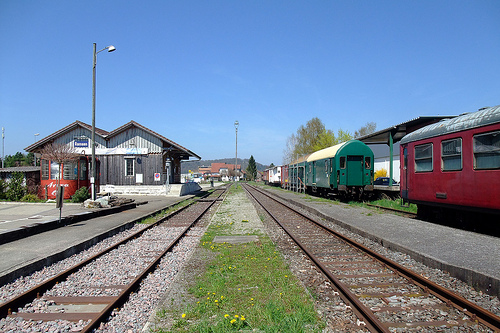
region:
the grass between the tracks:
[164, 232, 316, 330]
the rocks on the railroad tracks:
[0, 222, 211, 331]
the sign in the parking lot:
[51, 184, 66, 220]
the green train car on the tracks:
[286, 153, 374, 196]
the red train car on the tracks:
[396, 123, 498, 208]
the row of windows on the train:
[414, 125, 498, 167]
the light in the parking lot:
[93, 26, 115, 205]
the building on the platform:
[102, 119, 202, 181]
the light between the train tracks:
[228, 108, 243, 185]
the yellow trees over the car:
[371, 163, 393, 178]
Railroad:
[283, 198, 321, 256]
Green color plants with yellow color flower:
[201, 240, 280, 324]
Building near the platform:
[71, 118, 176, 170]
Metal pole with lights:
[83, 40, 125, 199]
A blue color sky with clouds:
[192, 0, 228, 140]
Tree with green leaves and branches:
[288, 103, 326, 147]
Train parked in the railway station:
[270, 111, 494, 202]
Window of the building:
[121, 153, 141, 185]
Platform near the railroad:
[14, 200, 50, 256]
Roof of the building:
[156, 128, 183, 150]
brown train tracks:
[236, 180, 499, 331]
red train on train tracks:
[391, 105, 497, 221]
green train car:
[283, 137, 380, 199]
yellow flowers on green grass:
[192, 285, 265, 328]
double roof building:
[15, 115, 204, 195]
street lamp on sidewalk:
[81, 37, 128, 205]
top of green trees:
[283, 113, 389, 159]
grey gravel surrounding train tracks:
[1, 223, 165, 331]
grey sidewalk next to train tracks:
[266, 185, 497, 296]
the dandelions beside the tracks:
[194, 290, 255, 328]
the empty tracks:
[260, 198, 470, 331]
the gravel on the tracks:
[69, 208, 184, 302]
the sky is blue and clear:
[2, 1, 494, 107]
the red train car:
[393, 120, 496, 202]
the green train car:
[302, 137, 382, 191]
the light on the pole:
[80, 39, 121, 187]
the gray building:
[22, 115, 193, 181]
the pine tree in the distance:
[237, 150, 261, 178]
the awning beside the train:
[343, 115, 436, 142]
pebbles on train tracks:
[90, 240, 150, 297]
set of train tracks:
[153, 185, 224, 248]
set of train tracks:
[271, 189, 384, 319]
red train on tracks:
[385, 111, 491, 211]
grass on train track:
[369, 191, 410, 226]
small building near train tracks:
[37, 111, 199, 204]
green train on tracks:
[279, 136, 384, 217]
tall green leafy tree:
[296, 117, 336, 151]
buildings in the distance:
[191, 158, 243, 190]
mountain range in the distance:
[176, 150, 264, 184]